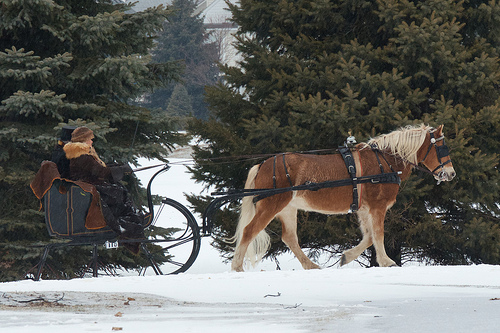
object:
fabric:
[30, 159, 108, 230]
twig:
[4, 274, 89, 317]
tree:
[193, 2, 499, 267]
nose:
[448, 171, 457, 178]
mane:
[359, 123, 436, 168]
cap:
[71, 126, 95, 142]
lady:
[62, 127, 132, 228]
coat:
[54, 142, 72, 179]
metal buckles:
[344, 154, 351, 158]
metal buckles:
[349, 165, 355, 173]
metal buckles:
[352, 188, 358, 192]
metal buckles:
[352, 204, 358, 208]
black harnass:
[336, 147, 358, 213]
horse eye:
[437, 145, 449, 157]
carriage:
[25, 159, 201, 282]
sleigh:
[24, 152, 403, 264]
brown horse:
[229, 123, 457, 272]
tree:
[0, 0, 229, 284]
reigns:
[104, 143, 401, 199]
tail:
[222, 163, 270, 271]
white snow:
[0, 262, 499, 333]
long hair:
[358, 122, 434, 164]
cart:
[28, 159, 201, 282]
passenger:
[47, 128, 72, 177]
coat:
[62, 140, 125, 186]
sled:
[28, 159, 202, 283]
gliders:
[25, 194, 201, 282]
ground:
[2, 130, 498, 331]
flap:
[432, 136, 451, 160]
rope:
[108, 163, 172, 229]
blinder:
[435, 139, 450, 164]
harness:
[210, 141, 403, 213]